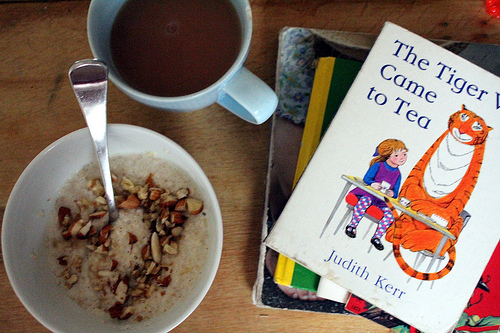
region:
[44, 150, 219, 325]
oatmeal and pecans on top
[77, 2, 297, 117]
mug of coffee with a bubble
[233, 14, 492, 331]
books stacked on top of each other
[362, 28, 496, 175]
book titled the tiger came to tea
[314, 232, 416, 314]
book anther named judith kerr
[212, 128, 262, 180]
wood grain from table top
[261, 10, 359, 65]
worn out corner of a book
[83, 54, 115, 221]
silver spoon shinny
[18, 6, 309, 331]
breakfast food on a wooden table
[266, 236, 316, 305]
end of a hard covered book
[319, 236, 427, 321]
The words Judith Kerr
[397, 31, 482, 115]
The words The Tiger on the book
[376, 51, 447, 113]
The words came on the book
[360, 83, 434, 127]
The words to tea on the book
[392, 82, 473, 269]
The tiger that is on the book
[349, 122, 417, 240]
The little girl that is on the book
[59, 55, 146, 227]
The spoon in the oatmeal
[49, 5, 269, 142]
The coffee on the table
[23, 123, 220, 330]
The bowl of the oatmeal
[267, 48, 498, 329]
A stack of books on the table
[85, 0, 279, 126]
the blue cup with liquid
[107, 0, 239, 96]
the liquid in the blue cup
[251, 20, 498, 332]
the pile of books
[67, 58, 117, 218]
the utensil in the bowl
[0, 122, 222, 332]
the bowl with food in it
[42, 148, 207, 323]
the food in the bowl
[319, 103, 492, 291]
the picture on the book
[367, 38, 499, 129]
the title of the book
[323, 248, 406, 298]
the author of the book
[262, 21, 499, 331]
the book at the top of the pile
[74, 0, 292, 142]
cup of coffee on table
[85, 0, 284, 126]
coffee in side cup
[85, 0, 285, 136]
blue coffee mug on table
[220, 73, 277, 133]
large blue handle of mug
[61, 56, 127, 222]
silver end of spoon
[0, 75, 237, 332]
spoon in a white bowl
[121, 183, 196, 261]
nuts in a bowl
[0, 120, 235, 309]
small white bowl on table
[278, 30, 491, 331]
books stacked on table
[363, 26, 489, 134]
blue writing on book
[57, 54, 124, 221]
silver metal spoon handle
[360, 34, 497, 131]
book title on cover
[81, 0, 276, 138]
coffee mug sitting on table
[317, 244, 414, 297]
book author on cover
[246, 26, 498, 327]
stack of books on wooden table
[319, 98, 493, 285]
image on cover of book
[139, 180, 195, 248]
chopped nuts on top of food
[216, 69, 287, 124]
blue handle on coffee mug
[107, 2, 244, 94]
coffee in mug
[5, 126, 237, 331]
food in white serving bowl